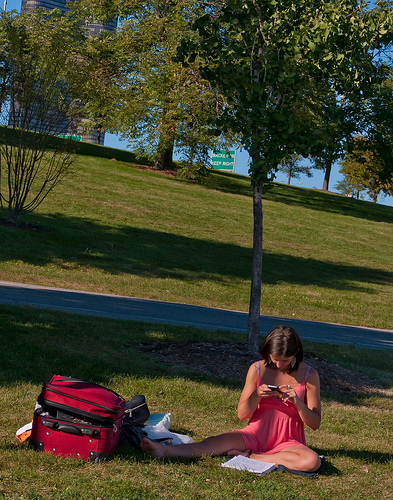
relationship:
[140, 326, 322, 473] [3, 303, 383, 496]
lady sitting in grass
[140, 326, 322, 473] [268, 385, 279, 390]
lady looking down at cell phone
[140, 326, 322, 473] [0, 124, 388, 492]
lady looking down at grass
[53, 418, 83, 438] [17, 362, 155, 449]
handle on luggage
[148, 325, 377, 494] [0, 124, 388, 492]
lady on grass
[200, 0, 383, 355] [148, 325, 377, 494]
tree behind lady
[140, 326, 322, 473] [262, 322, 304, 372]
lady with hair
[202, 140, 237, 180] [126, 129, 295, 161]
green sign by road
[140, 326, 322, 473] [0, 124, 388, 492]
lady on grass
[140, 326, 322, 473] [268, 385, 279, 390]
lady using cell phone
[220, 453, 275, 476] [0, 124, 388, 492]
book on grass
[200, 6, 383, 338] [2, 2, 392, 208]
tree in background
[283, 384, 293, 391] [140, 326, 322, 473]
ring on lady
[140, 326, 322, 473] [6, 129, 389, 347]
lady on grass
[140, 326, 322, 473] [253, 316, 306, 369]
lady has hair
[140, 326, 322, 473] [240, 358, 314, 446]
lady wearing dress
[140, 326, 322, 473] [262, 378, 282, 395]
lady looking at cell phone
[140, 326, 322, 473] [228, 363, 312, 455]
lady wearing dress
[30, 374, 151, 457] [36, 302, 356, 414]
luggage on grass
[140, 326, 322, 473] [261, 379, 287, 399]
lady looking at cellphone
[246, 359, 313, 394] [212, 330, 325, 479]
bra underneath dress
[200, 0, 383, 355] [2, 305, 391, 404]
tree with shade